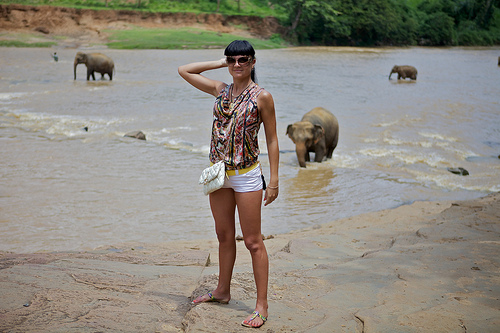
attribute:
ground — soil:
[0, 181, 499, 326]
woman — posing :
[184, 39, 281, 330]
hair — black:
[224, 35, 257, 86]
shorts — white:
[210, 171, 265, 192]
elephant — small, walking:
[287, 105, 335, 167]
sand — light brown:
[4, 193, 494, 333]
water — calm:
[2, 48, 500, 154]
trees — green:
[295, 4, 499, 51]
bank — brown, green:
[2, 2, 286, 54]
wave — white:
[4, 81, 103, 137]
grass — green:
[115, 31, 205, 52]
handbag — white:
[199, 153, 232, 192]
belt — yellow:
[222, 160, 261, 174]